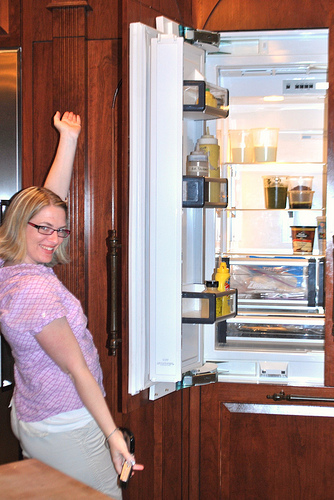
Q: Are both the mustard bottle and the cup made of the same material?
A: Yes, both the mustard bottle and the cup are made of plastic.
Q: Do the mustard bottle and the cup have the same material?
A: Yes, both the mustard bottle and the cup are made of plastic.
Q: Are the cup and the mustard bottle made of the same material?
A: Yes, both the cup and the mustard bottle are made of plastic.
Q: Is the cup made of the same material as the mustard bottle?
A: Yes, both the cup and the mustard bottle are made of plastic.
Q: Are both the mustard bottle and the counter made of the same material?
A: No, the mustard bottle is made of plastic and the counter is made of wood.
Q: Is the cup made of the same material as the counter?
A: No, the cup is made of plastic and the counter is made of wood.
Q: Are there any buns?
A: No, there are no buns.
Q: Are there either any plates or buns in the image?
A: No, there are no buns or plates.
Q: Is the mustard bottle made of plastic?
A: Yes, the mustard bottle is made of plastic.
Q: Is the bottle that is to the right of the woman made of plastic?
A: Yes, the mustard bottle is made of plastic.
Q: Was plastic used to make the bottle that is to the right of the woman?
A: Yes, the mustard bottle is made of plastic.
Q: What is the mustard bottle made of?
A: The mustard bottle is made of plastic.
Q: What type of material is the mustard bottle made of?
A: The mustard bottle is made of plastic.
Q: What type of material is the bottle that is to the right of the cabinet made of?
A: The mustard bottle is made of plastic.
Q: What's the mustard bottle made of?
A: The mustard bottle is made of plastic.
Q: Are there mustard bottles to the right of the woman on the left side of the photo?
A: Yes, there is a mustard bottle to the right of the woman.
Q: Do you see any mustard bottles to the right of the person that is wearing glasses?
A: Yes, there is a mustard bottle to the right of the woman.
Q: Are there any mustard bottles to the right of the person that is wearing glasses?
A: Yes, there is a mustard bottle to the right of the woman.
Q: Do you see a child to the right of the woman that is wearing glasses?
A: No, there is a mustard bottle to the right of the woman.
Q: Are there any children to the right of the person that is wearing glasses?
A: No, there is a mustard bottle to the right of the woman.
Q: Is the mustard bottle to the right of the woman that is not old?
A: Yes, the mustard bottle is to the right of the woman.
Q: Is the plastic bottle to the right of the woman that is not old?
A: Yes, the mustard bottle is to the right of the woman.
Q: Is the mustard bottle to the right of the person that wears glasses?
A: Yes, the mustard bottle is to the right of the woman.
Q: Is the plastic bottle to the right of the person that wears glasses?
A: Yes, the mustard bottle is to the right of the woman.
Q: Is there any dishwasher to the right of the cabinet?
A: No, there is a mustard bottle to the right of the cabinet.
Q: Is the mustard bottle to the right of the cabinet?
A: Yes, the mustard bottle is to the right of the cabinet.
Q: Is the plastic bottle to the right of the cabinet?
A: Yes, the mustard bottle is to the right of the cabinet.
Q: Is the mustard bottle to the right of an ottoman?
A: No, the mustard bottle is to the right of the cabinet.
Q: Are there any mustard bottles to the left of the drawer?
A: Yes, there is a mustard bottle to the left of the drawer.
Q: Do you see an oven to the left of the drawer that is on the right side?
A: No, there is a mustard bottle to the left of the drawer.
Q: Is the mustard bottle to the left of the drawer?
A: Yes, the mustard bottle is to the left of the drawer.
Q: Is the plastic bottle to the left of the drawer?
A: Yes, the mustard bottle is to the left of the drawer.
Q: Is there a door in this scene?
A: Yes, there is a door.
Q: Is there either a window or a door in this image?
A: Yes, there is a door.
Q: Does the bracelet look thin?
A: Yes, the bracelet is thin.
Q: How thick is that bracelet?
A: The bracelet is thin.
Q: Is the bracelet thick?
A: No, the bracelet is thin.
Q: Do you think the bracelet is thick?
A: No, the bracelet is thin.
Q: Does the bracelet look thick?
A: No, the bracelet is thin.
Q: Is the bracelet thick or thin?
A: The bracelet is thin.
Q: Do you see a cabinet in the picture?
A: Yes, there is a cabinet.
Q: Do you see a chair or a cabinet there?
A: Yes, there is a cabinet.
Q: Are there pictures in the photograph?
A: No, there are no pictures.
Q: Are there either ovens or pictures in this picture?
A: No, there are no pictures or ovens.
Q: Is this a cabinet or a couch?
A: This is a cabinet.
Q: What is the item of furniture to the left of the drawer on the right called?
A: The piece of furniture is a cabinet.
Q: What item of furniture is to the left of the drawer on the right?
A: The piece of furniture is a cabinet.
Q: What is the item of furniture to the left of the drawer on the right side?
A: The piece of furniture is a cabinet.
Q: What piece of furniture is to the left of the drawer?
A: The piece of furniture is a cabinet.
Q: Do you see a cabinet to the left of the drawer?
A: Yes, there is a cabinet to the left of the drawer.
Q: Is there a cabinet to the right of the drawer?
A: No, the cabinet is to the left of the drawer.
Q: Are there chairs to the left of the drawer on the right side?
A: No, there is a cabinet to the left of the drawer.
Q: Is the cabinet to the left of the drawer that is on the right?
A: Yes, the cabinet is to the left of the drawer.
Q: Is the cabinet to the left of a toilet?
A: No, the cabinet is to the left of the drawer.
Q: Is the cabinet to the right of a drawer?
A: No, the cabinet is to the left of a drawer.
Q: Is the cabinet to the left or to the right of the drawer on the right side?
A: The cabinet is to the left of the drawer.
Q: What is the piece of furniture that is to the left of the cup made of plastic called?
A: The piece of furniture is a cabinet.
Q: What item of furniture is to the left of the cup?
A: The piece of furniture is a cabinet.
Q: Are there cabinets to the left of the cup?
A: Yes, there is a cabinet to the left of the cup.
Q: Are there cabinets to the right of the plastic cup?
A: No, the cabinet is to the left of the cup.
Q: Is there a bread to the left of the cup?
A: No, there is a cabinet to the left of the cup.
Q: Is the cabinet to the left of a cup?
A: Yes, the cabinet is to the left of a cup.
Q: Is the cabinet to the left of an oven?
A: No, the cabinet is to the left of a cup.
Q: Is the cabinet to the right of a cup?
A: No, the cabinet is to the left of a cup.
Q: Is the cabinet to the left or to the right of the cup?
A: The cabinet is to the left of the cup.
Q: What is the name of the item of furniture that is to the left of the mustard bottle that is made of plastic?
A: The piece of furniture is a cabinet.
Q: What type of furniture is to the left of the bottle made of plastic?
A: The piece of furniture is a cabinet.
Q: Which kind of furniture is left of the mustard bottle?
A: The piece of furniture is a cabinet.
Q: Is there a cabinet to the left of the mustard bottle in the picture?
A: Yes, there is a cabinet to the left of the mustard bottle.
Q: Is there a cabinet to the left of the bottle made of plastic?
A: Yes, there is a cabinet to the left of the mustard bottle.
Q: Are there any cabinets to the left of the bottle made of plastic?
A: Yes, there is a cabinet to the left of the mustard bottle.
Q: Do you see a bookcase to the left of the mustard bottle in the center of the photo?
A: No, there is a cabinet to the left of the mustard bottle.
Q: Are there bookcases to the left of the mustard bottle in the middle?
A: No, there is a cabinet to the left of the mustard bottle.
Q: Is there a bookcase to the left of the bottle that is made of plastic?
A: No, there is a cabinet to the left of the mustard bottle.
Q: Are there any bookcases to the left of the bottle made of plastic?
A: No, there is a cabinet to the left of the mustard bottle.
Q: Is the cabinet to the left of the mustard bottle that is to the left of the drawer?
A: Yes, the cabinet is to the left of the mustard bottle.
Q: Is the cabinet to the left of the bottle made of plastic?
A: Yes, the cabinet is to the left of the mustard bottle.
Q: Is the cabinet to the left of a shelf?
A: No, the cabinet is to the left of the mustard bottle.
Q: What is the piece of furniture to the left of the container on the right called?
A: The piece of furniture is a cabinet.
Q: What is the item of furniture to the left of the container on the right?
A: The piece of furniture is a cabinet.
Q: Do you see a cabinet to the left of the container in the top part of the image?
A: Yes, there is a cabinet to the left of the container.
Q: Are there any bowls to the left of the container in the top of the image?
A: No, there is a cabinet to the left of the container.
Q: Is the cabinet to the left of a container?
A: Yes, the cabinet is to the left of a container.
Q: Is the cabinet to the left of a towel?
A: No, the cabinet is to the left of a container.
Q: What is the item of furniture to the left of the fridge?
A: The piece of furniture is a cabinet.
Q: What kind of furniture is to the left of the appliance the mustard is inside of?
A: The piece of furniture is a cabinet.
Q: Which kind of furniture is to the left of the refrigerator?
A: The piece of furniture is a cabinet.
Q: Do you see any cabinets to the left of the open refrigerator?
A: Yes, there is a cabinet to the left of the fridge.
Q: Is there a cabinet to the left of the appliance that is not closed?
A: Yes, there is a cabinet to the left of the fridge.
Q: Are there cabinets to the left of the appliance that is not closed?
A: Yes, there is a cabinet to the left of the fridge.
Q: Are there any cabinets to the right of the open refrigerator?
A: No, the cabinet is to the left of the fridge.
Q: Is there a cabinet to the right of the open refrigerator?
A: No, the cabinet is to the left of the fridge.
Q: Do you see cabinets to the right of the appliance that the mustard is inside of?
A: No, the cabinet is to the left of the fridge.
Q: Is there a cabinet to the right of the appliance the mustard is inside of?
A: No, the cabinet is to the left of the fridge.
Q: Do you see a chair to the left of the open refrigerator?
A: No, there is a cabinet to the left of the freezer.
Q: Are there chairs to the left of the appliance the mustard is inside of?
A: No, there is a cabinet to the left of the freezer.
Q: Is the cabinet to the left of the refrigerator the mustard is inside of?
A: Yes, the cabinet is to the left of the refrigerator.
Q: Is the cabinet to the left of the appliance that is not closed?
A: Yes, the cabinet is to the left of the refrigerator.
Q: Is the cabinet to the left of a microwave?
A: No, the cabinet is to the left of the refrigerator.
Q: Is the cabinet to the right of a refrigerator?
A: No, the cabinet is to the left of a refrigerator.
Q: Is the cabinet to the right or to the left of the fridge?
A: The cabinet is to the left of the fridge.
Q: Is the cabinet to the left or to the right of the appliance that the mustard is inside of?
A: The cabinet is to the left of the fridge.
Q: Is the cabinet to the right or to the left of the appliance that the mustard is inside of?
A: The cabinet is to the left of the fridge.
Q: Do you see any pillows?
A: No, there are no pillows.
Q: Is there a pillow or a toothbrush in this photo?
A: No, there are no pillows or toothbrushes.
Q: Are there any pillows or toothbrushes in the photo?
A: No, there are no pillows or toothbrushes.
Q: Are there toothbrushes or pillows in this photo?
A: No, there are no pillows or toothbrushes.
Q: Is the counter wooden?
A: Yes, the counter is wooden.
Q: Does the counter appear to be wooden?
A: Yes, the counter is wooden.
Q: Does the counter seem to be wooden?
A: Yes, the counter is wooden.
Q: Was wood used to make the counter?
A: Yes, the counter is made of wood.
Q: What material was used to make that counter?
A: The counter is made of wood.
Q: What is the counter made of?
A: The counter is made of wood.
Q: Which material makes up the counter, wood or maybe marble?
A: The counter is made of wood.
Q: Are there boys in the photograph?
A: No, there are no boys.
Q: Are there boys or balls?
A: No, there are no boys or balls.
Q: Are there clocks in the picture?
A: No, there are no clocks.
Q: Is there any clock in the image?
A: No, there are no clocks.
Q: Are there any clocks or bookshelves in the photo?
A: No, there are no clocks or bookshelves.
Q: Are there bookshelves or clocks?
A: No, there are no clocks or bookshelves.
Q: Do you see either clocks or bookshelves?
A: No, there are no clocks or bookshelves.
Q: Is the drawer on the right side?
A: Yes, the drawer is on the right of the image.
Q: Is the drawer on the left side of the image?
A: No, the drawer is on the right of the image.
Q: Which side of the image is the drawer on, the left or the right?
A: The drawer is on the right of the image.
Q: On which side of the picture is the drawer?
A: The drawer is on the right of the image.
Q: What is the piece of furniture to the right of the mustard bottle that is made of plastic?
A: The piece of furniture is a drawer.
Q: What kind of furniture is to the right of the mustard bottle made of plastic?
A: The piece of furniture is a drawer.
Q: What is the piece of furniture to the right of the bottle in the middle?
A: The piece of furniture is a drawer.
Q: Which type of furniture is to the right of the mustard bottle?
A: The piece of furniture is a drawer.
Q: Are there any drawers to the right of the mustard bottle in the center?
A: Yes, there is a drawer to the right of the mustard bottle.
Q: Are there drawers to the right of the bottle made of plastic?
A: Yes, there is a drawer to the right of the mustard bottle.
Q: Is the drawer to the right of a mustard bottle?
A: Yes, the drawer is to the right of a mustard bottle.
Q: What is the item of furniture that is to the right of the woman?
A: The piece of furniture is a drawer.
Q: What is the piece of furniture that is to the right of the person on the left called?
A: The piece of furniture is a drawer.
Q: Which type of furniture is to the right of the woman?
A: The piece of furniture is a drawer.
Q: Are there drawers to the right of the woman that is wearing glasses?
A: Yes, there is a drawer to the right of the woman.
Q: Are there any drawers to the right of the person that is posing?
A: Yes, there is a drawer to the right of the woman.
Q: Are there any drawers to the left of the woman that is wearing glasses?
A: No, the drawer is to the right of the woman.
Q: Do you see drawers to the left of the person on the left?
A: No, the drawer is to the right of the woman.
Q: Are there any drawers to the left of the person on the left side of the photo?
A: No, the drawer is to the right of the woman.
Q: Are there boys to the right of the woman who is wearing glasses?
A: No, there is a drawer to the right of the woman.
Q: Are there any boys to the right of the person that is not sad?
A: No, there is a drawer to the right of the woman.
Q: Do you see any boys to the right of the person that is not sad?
A: No, there is a drawer to the right of the woman.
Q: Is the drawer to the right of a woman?
A: Yes, the drawer is to the right of a woman.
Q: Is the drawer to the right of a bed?
A: No, the drawer is to the right of a woman.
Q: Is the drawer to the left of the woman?
A: No, the drawer is to the right of the woman.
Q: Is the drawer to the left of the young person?
A: No, the drawer is to the right of the woman.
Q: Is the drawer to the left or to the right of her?
A: The drawer is to the right of the woman.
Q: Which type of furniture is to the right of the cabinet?
A: The piece of furniture is a drawer.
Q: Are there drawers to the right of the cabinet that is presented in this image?
A: Yes, there is a drawer to the right of the cabinet.